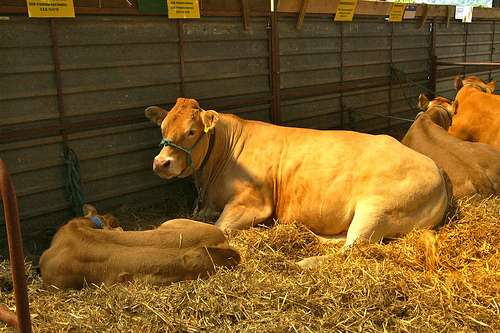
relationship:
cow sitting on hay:
[139, 90, 462, 272] [246, 230, 416, 330]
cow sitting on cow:
[33, 197, 248, 288] [130, 86, 445, 248]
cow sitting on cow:
[33, 197, 248, 288] [392, 85, 497, 193]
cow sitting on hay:
[33, 197, 248, 288] [97, 287, 492, 327]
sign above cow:
[158, 49, 210, 73] [120, 74, 462, 300]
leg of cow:
[283, 203, 390, 273] [136, 89, 462, 260]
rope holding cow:
[57, 138, 94, 213] [39, 188, 254, 311]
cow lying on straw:
[136, 89, 462, 260] [204, 264, 496, 329]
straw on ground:
[3, 182, 498, 330] [4, 210, 495, 325]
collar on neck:
[80, 210, 106, 229] [76, 207, 106, 227]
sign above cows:
[25, 0, 79, 20] [140, 94, 448, 271]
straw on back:
[175, 231, 190, 248] [91, 196, 237, 246]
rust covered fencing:
[4, 112, 61, 154] [231, 36, 363, 109]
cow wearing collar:
[37, 203, 243, 295] [82, 208, 111, 226]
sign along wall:
[25, 0, 79, 20] [4, 1, 438, 101]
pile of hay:
[297, 227, 439, 317] [237, 231, 490, 331]